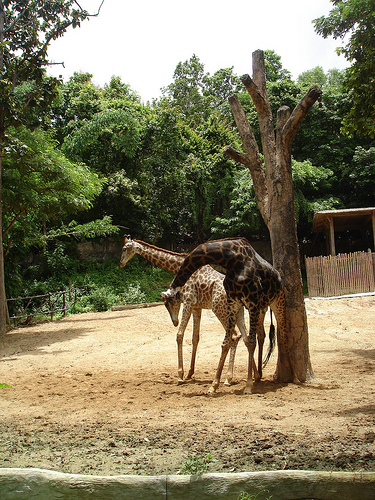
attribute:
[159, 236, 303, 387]
giraffes — young, dark brown, standing, dark colored, dark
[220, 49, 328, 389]
tree — dead, growing, large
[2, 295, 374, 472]
ground — muddy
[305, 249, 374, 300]
fence — small, wooden, dark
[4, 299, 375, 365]
sand — dry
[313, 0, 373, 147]
trees — tall, around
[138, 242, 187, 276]
neck — long, down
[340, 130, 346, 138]
leaves — lush, green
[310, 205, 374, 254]
shelter — open air, cover, small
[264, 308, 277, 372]
tail — bushy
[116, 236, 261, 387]
giraffe — light brown, light colored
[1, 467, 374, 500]
wall — concrete, short